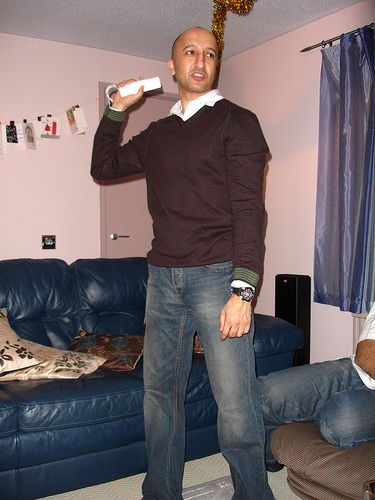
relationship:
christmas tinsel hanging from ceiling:
[211, 0, 258, 55] [0, 0, 365, 63]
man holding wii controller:
[89, 25, 271, 499] [105, 75, 163, 104]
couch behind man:
[0, 255, 306, 500] [89, 25, 271, 499]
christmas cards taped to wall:
[0, 104, 89, 149] [0, 30, 179, 264]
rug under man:
[181, 473, 236, 499] [89, 25, 271, 499]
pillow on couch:
[64, 326, 146, 371] [0, 255, 306, 500]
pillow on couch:
[0, 338, 108, 382] [0, 255, 306, 500]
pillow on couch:
[0, 305, 40, 378] [0, 255, 306, 500]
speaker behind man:
[276, 273, 311, 367] [89, 25, 271, 499]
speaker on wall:
[276, 273, 311, 367] [217, 0, 375, 366]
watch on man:
[230, 285, 255, 301] [89, 25, 271, 499]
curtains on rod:
[310, 22, 373, 314] [299, 21, 373, 53]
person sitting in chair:
[256, 301, 374, 472] [269, 419, 374, 500]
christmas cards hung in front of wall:
[0, 104, 89, 149] [0, 30, 179, 264]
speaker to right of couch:
[276, 273, 311, 367] [0, 255, 306, 500]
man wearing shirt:
[89, 25, 271, 499] [167, 89, 223, 123]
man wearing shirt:
[89, 25, 271, 499] [91, 96, 270, 288]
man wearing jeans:
[89, 25, 271, 499] [141, 261, 277, 499]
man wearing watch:
[89, 25, 271, 499] [230, 285, 255, 301]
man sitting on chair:
[256, 301, 374, 472] [269, 419, 374, 500]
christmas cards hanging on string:
[0, 104, 89, 149] [2, 97, 99, 125]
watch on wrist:
[230, 285, 255, 301] [230, 277, 255, 302]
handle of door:
[110, 232, 131, 242] [97, 80, 181, 259]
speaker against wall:
[276, 273, 311, 367] [217, 0, 375, 366]